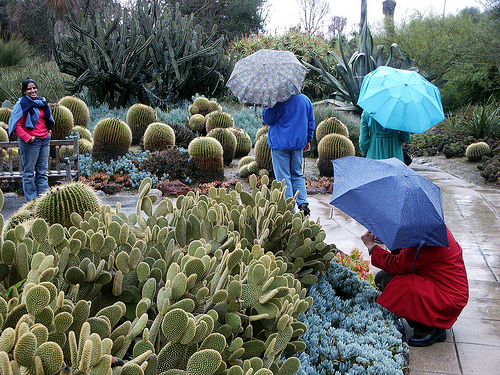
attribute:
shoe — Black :
[411, 322, 445, 346]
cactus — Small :
[461, 139, 495, 166]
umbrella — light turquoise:
[363, 68, 455, 134]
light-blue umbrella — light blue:
[359, 65, 445, 136]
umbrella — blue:
[325, 151, 450, 251]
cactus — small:
[184, 136, 226, 183]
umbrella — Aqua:
[354, 63, 452, 134]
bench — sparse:
[0, 132, 77, 195]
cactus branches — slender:
[50, 0, 235, 109]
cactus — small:
[141, 122, 176, 151]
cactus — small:
[190, 137, 222, 176]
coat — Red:
[373, 229, 468, 330]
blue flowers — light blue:
[292, 267, 411, 373]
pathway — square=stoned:
[446, 178, 488, 240]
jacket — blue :
[242, 83, 306, 138]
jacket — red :
[370, 210, 472, 355]